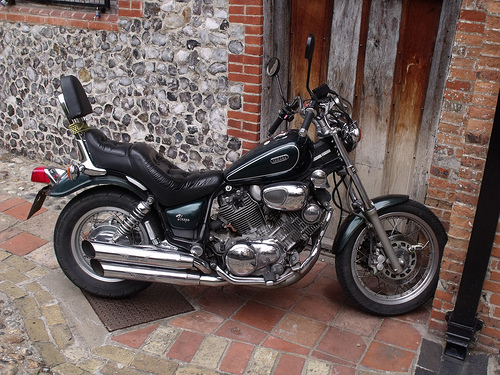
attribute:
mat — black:
[80, 279, 193, 332]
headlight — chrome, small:
[350, 127, 361, 142]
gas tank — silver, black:
[225, 127, 312, 188]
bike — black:
[21, 33, 452, 333]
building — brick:
[3, 6, 494, 352]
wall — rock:
[452, 20, 499, 122]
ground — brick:
[0, 196, 432, 373]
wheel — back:
[55, 184, 169, 307]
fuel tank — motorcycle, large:
[222, 129, 314, 182]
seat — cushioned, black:
[82, 129, 228, 199]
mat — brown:
[55, 289, 221, 325]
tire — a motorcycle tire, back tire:
[32, 179, 180, 293]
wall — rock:
[76, 35, 229, 146]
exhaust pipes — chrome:
[81, 239, 225, 289]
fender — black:
[329, 180, 412, 255]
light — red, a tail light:
[24, 163, 56, 187]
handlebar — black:
[260, 101, 297, 137]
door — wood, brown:
[293, 35, 420, 204]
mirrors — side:
[265, 27, 314, 78]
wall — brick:
[419, 0, 498, 350]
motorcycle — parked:
[19, 39, 451, 313]